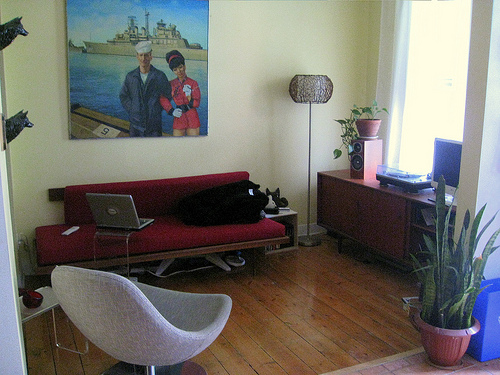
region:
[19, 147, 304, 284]
the couch is red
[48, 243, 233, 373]
the chair is gray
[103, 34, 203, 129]
painting of sailor and woman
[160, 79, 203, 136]
woman has red outfit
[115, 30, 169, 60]
the hat is white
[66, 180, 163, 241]
the laptop is gray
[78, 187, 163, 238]
laptop is on couch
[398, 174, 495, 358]
plant in brown container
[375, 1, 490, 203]
the curtains are drawn open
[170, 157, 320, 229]
black object on couch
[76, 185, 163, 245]
A laptop on the couch.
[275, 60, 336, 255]
A lamp.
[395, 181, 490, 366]
A broadleaf plant in a planter.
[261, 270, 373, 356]
Wood floors.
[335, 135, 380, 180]
A speaker.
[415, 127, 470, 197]
A small television.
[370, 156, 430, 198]
A record player on top of the cabinet.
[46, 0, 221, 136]
A large painting.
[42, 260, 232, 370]
A gray chair.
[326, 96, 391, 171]
A plant growing down the side of the speaker.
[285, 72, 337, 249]
a tall silver floor lamp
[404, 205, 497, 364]
a tall plant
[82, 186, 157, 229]
a gray laptop computer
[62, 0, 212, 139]
a large painting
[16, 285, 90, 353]
a small gray table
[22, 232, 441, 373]
brown hardwood floor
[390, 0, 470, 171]
a large living room window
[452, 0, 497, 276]
part of a white wall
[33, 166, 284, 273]
a small red and brown couch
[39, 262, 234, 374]
a gray chair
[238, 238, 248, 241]
edge of a seat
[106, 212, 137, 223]
back of a laptop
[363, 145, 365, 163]
edge of a speaker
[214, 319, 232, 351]
part of a floor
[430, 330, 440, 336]
edge of a vase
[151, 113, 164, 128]
part of a painting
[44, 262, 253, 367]
the chair is a whiteish grey color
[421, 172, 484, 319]
the plant has tall green leaves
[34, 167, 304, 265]
the couch is reddish maroon color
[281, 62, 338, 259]
the lamp has a brown shade cover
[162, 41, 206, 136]
the lady in the picture is wearing a red outfit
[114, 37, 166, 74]
the sailor is wearing a white hat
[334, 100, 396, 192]
the plant is sitting on a speaker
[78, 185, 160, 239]
the laptop is a silver color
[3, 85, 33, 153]
the wolf statue is hanging on the wall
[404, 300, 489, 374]
the pot is a reddish brown color